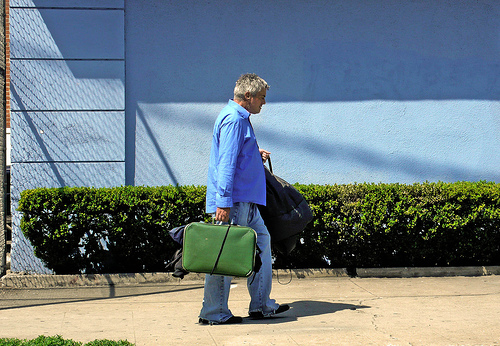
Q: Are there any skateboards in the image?
A: No, there are no skateboards.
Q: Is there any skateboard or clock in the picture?
A: No, there are no skateboards or clocks.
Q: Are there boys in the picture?
A: No, there are no boys.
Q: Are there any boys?
A: No, there are no boys.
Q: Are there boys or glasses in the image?
A: No, there are no boys or glasses.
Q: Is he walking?
A: Yes, the man is walking.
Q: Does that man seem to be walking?
A: Yes, the man is walking.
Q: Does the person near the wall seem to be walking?
A: Yes, the man is walking.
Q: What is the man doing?
A: The man is walking.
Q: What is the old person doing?
A: The man is walking.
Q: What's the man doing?
A: The man is walking.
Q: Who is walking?
A: The man is walking.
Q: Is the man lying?
A: No, the man is walking.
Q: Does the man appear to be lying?
A: No, the man is walking.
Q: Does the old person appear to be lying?
A: No, the man is walking.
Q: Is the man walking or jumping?
A: The man is walking.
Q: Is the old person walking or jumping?
A: The man is walking.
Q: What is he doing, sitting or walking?
A: The man is walking.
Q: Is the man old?
A: Yes, the man is old.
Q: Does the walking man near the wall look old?
A: Yes, the man is old.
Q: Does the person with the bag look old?
A: Yes, the man is old.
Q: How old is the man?
A: The man is old.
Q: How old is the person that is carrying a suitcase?
A: The man is old.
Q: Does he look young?
A: No, the man is old.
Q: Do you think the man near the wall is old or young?
A: The man is old.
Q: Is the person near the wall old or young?
A: The man is old.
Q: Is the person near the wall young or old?
A: The man is old.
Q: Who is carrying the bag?
A: The man is carrying the bag.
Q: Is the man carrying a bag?
A: Yes, the man is carrying a bag.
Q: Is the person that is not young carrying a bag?
A: Yes, the man is carrying a bag.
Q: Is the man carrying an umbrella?
A: No, the man is carrying a bag.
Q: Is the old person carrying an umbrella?
A: No, the man is carrying a bag.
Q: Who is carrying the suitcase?
A: The man is carrying the suitcase.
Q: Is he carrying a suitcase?
A: Yes, the man is carrying a suitcase.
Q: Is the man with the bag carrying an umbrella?
A: No, the man is carrying a suitcase.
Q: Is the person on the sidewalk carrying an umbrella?
A: No, the man is carrying a suitcase.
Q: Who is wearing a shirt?
A: The man is wearing a shirt.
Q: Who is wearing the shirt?
A: The man is wearing a shirt.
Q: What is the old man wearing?
A: The man is wearing a shirt.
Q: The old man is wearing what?
A: The man is wearing a shirt.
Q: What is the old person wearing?
A: The man is wearing a shirt.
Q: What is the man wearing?
A: The man is wearing a shirt.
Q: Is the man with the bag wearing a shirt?
A: Yes, the man is wearing a shirt.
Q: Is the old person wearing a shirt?
A: Yes, the man is wearing a shirt.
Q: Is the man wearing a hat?
A: No, the man is wearing a shirt.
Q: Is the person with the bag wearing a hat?
A: No, the man is wearing a shirt.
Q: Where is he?
A: The man is on the sidewalk.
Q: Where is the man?
A: The man is on the sidewalk.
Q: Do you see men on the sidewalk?
A: Yes, there is a man on the sidewalk.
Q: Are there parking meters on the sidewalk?
A: No, there is a man on the sidewalk.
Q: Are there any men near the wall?
A: Yes, there is a man near the wall.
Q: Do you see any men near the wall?
A: Yes, there is a man near the wall.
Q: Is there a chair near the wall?
A: No, there is a man near the wall.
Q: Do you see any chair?
A: No, there are no chairs.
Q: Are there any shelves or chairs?
A: No, there are no chairs or shelves.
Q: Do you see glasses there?
A: No, there are no glasses.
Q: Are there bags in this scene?
A: Yes, there is a bag.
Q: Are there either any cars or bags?
A: Yes, there is a bag.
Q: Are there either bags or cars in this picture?
A: Yes, there is a bag.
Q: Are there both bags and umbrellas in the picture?
A: No, there is a bag but no umbrellas.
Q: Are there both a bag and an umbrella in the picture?
A: No, there is a bag but no umbrellas.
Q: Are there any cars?
A: No, there are no cars.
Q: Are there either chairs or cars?
A: No, there are no cars or chairs.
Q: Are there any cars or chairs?
A: No, there are no cars or chairs.